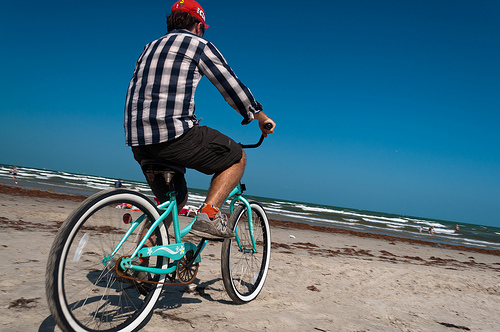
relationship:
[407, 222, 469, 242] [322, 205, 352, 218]
people in water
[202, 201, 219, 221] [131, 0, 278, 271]
sock on man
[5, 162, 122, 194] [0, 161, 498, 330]
people walking on beach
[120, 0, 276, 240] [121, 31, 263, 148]
man has shirt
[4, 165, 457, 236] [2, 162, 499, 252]
waves on water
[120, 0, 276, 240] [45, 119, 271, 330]
man riding bike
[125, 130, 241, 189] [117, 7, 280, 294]
shorts on person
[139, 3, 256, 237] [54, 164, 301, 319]
man riding a bicycle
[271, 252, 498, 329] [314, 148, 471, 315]
sand of beach